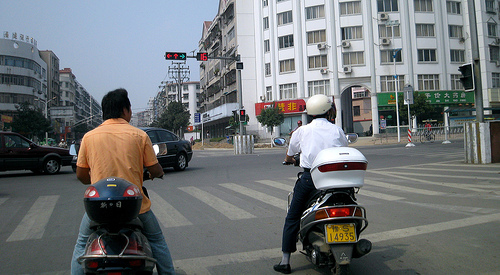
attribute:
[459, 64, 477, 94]
light — for traffic, to stop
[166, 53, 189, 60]
light — for traffic, to stop, for caution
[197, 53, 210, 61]
light — for traffic, to stop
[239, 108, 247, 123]
light — for traffic, to stop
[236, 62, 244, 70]
light — for traffic, to stop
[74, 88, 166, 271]
man — on left side, riding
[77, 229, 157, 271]
moped — for riding, mean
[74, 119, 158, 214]
shirt — orange, on rider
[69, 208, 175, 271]
jeans — blue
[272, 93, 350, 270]
person — on right side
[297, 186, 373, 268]
moped — for riding, mean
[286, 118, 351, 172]
shirt — white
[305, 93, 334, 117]
helmet — white, for moped, hard, for mopeds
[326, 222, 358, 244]
plate — for license, for moped, yellow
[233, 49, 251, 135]
pole — for utility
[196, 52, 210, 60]
number — 16, lighted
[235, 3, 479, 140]
building — white, located on corner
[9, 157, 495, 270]
lines — white, painted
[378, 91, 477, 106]
sign — green, for street, white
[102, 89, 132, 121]
hair — black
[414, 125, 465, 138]
rack — for bikes, metal